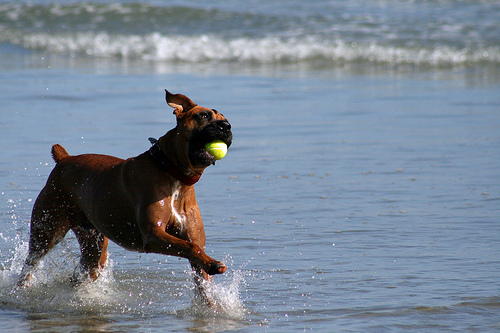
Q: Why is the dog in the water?
A: Playing.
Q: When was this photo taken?
A: During the day.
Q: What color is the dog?
A: Brown.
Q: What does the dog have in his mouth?
A: A tennis ball.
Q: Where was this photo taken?
A: At the beach.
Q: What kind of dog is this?
A: Boxer.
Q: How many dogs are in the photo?
A: Just 1.